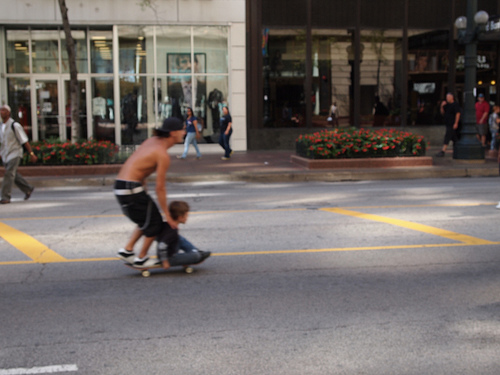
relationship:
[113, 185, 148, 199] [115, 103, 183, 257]
white belt on skater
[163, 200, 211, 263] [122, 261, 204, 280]
child sitting on skateboard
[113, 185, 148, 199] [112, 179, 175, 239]
white belt with pants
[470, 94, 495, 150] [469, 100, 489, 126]
person in red shirt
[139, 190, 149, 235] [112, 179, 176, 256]
chain on pants